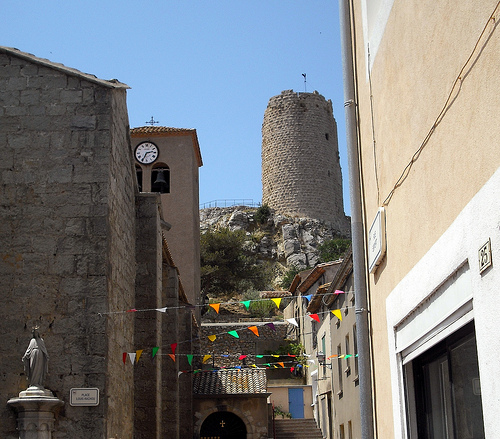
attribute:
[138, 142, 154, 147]
numerals — black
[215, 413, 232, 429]
cross — golden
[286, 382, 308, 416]
door — blue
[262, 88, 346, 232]
tower — brick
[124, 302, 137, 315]
flag — colorful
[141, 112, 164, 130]
cross — gold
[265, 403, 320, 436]
stairway — concrete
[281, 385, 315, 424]
door — blue, wooden, arched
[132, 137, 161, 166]
clock — white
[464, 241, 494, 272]
number — 25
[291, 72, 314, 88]
flags — multi-colored, hanging, colorful, triangle, orange, green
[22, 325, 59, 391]
structure — grey, concrete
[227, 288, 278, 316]
hill — steep, rocky